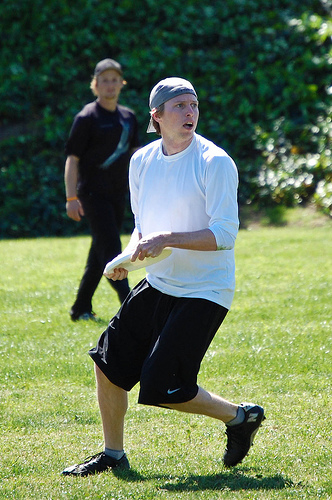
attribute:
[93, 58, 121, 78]
cap — blue, backward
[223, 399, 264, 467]
shoe — black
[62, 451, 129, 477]
shoe — black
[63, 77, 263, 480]
male — playing, looking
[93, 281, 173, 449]
leg — pale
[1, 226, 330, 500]
grass — green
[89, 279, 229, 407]
shorts — black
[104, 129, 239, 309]
shirt — white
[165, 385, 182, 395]
nike swoosh — white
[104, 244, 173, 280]
frisbee — plastic, white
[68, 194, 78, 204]
wristband — orange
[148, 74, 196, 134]
hat — gray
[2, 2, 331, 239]
tree — thick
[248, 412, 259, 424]
sign — white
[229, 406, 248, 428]
sock — gray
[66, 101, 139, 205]
shirt — black